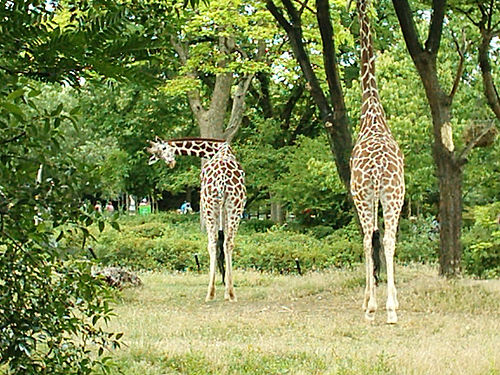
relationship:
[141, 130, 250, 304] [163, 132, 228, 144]
giraffe has mane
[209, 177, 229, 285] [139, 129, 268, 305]
tail of giraffe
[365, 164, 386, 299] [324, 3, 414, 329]
tail of giraffe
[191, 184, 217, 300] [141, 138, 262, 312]
legs of giraffe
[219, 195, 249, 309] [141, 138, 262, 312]
legs of giraffe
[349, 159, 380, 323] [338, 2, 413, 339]
legs of giraffe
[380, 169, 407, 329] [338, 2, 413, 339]
legs of giraffe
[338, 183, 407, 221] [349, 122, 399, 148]
back of giraffe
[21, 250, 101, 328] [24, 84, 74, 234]
leaves on a tree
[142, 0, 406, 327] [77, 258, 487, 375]
two giraffes in grass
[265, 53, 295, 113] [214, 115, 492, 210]
sky behind trees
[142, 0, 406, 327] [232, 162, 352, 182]
two giraffes standing together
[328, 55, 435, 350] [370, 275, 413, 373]
one tall giraffes standing up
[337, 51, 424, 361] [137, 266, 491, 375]
one tall giraffe in grass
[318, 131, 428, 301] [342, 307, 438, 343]
one giraffe standing in grass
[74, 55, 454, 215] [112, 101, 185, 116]
trees with green leaves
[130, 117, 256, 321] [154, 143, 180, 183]
one giraffe looking backwards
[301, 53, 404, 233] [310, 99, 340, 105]
one giraffe looking up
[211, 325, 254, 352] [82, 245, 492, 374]
brown and green grass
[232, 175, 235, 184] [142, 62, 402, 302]
brown and white giraffes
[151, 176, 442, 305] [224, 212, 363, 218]
no spots on legs of giraffes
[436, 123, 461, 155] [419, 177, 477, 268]
light patch on tree trunk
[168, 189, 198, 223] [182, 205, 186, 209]
someone in background wears blue shirt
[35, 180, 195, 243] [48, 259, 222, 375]
athletic field in background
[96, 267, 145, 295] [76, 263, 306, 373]
one rock in grass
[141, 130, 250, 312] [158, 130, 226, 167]
giraffe cranes its neck